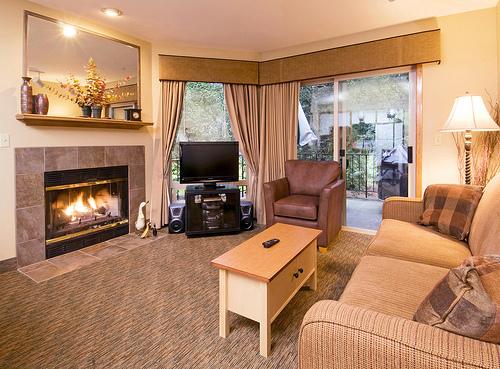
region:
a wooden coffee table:
[215, 218, 322, 350]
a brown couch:
[302, 171, 497, 361]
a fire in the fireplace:
[47, 163, 125, 259]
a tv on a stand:
[175, 136, 243, 234]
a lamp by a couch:
[439, 90, 494, 181]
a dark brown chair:
[262, 157, 343, 224]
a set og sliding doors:
[294, 68, 424, 147]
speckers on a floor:
[168, 203, 182, 235]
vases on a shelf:
[15, 76, 51, 118]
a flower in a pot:
[47, 56, 137, 124]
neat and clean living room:
[5, 4, 498, 364]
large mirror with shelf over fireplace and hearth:
[18, 13, 149, 273]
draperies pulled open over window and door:
[159, 54, 422, 234]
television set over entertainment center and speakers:
[167, 123, 256, 238]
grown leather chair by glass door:
[262, 146, 347, 243]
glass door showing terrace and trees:
[293, 68, 418, 233]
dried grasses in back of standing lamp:
[436, 80, 498, 179]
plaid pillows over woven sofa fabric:
[298, 180, 497, 365]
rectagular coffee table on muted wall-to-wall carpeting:
[3, 220, 378, 366]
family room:
[6, 2, 495, 367]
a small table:
[206, 217, 324, 357]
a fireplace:
[11, 142, 173, 286]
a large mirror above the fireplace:
[18, 5, 147, 134]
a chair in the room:
[257, 153, 348, 253]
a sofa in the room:
[293, 173, 498, 365]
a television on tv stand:
[175, 135, 241, 185]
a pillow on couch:
[412, 175, 483, 245]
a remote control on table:
[257, 235, 279, 250]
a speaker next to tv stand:
[165, 200, 187, 236]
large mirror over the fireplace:
[21, 10, 140, 120]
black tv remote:
[262, 238, 278, 249]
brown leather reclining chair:
[260, 160, 342, 246]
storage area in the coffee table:
[270, 238, 318, 320]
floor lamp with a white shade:
[440, 93, 497, 187]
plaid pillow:
[420, 183, 484, 240]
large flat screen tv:
[179, 140, 239, 182]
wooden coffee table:
[211, 220, 322, 357]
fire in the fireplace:
[43, 164, 129, 244]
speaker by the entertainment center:
[164, 201, 186, 234]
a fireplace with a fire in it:
[32, 150, 145, 270]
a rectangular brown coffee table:
[187, 205, 329, 349]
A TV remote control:
[256, 230, 284, 255]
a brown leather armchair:
[259, 154, 351, 255]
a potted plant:
[44, 59, 139, 125]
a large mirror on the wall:
[12, 8, 154, 142]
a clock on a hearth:
[117, 100, 142, 125]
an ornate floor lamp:
[405, 81, 498, 216]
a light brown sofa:
[297, 170, 487, 364]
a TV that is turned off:
[161, 133, 256, 191]